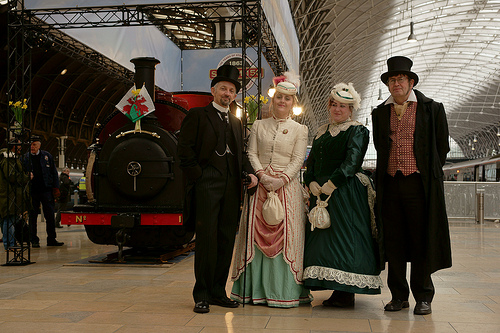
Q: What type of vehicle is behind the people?
A: A train.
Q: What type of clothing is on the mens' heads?
A: Top hats.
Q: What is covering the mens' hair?
A: Top hats.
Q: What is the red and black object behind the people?
A: A train.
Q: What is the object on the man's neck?
A: A tie.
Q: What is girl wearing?
A: Dress.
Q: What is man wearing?
A: Hat.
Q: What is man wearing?
A: Suit.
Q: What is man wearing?
A: Hat.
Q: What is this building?
A: Mall.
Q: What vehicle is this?
A: Train.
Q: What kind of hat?
A: Top hat.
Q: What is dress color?
A: White.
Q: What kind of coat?
A: Trench.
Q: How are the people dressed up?
A: Period clothing.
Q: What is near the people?
A: Front of the train.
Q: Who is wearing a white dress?
A: A woman.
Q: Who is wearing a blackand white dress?
A: A woman.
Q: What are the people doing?
A: Looking at the camera.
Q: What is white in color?
A: Roof of the building.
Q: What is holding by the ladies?
A: A purse.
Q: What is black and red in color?
A: A train.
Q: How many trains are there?
A: 1.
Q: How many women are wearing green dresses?
A: 1.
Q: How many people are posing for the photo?
A: 4.